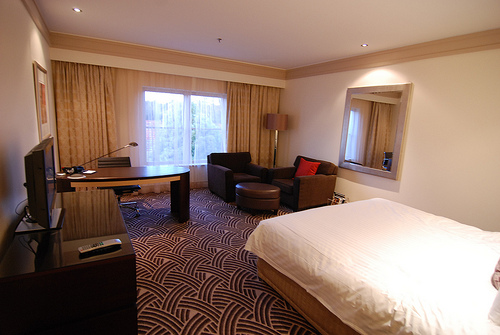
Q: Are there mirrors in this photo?
A: Yes, there is a mirror.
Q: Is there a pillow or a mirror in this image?
A: Yes, there is a mirror.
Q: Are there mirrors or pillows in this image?
A: Yes, there is a mirror.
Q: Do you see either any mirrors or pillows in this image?
A: Yes, there is a mirror.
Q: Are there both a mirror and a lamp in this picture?
A: Yes, there are both a mirror and a lamp.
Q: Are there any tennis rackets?
A: No, there are no tennis rackets.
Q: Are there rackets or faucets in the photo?
A: No, there are no rackets or faucets.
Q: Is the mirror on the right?
A: Yes, the mirror is on the right of the image.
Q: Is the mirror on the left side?
A: No, the mirror is on the right of the image.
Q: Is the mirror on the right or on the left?
A: The mirror is on the right of the image.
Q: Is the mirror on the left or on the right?
A: The mirror is on the right of the image.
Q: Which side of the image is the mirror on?
A: The mirror is on the right of the image.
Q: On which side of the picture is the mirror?
A: The mirror is on the right of the image.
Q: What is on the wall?
A: The mirror is on the wall.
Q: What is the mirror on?
A: The mirror is on the wall.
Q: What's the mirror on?
A: The mirror is on the wall.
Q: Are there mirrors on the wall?
A: Yes, there is a mirror on the wall.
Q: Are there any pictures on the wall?
A: No, there is a mirror on the wall.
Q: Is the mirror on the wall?
A: Yes, the mirror is on the wall.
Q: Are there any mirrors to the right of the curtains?
A: Yes, there is a mirror to the right of the curtains.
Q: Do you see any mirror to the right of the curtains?
A: Yes, there is a mirror to the right of the curtains.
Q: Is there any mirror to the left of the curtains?
A: No, the mirror is to the right of the curtains.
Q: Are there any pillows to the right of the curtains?
A: No, there is a mirror to the right of the curtains.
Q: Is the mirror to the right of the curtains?
A: Yes, the mirror is to the right of the curtains.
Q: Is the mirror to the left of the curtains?
A: No, the mirror is to the right of the curtains.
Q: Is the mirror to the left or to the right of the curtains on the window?
A: The mirror is to the right of the curtains.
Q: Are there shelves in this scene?
A: No, there are no shelves.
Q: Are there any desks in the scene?
A: Yes, there is a desk.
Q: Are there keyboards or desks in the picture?
A: Yes, there is a desk.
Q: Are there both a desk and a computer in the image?
A: No, there is a desk but no computers.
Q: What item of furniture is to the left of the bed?
A: The piece of furniture is a desk.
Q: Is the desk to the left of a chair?
A: No, the desk is to the left of the bed.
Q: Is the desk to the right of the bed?
A: No, the desk is to the left of the bed.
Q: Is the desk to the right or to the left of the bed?
A: The desk is to the left of the bed.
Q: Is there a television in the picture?
A: Yes, there is a television.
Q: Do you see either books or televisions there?
A: Yes, there is a television.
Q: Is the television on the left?
A: Yes, the television is on the left of the image.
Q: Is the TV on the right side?
A: No, the TV is on the left of the image.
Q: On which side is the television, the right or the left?
A: The television is on the left of the image.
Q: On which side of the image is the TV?
A: The TV is on the left of the image.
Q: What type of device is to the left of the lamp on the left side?
A: The device is a television.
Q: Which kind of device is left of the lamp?
A: The device is a television.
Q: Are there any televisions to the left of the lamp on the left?
A: Yes, there is a television to the left of the lamp.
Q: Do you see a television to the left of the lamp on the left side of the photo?
A: Yes, there is a television to the left of the lamp.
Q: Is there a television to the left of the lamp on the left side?
A: Yes, there is a television to the left of the lamp.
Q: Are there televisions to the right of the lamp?
A: No, the television is to the left of the lamp.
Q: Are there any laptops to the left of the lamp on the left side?
A: No, there is a television to the left of the lamp.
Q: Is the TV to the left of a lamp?
A: Yes, the TV is to the left of a lamp.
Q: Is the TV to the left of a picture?
A: No, the TV is to the left of a lamp.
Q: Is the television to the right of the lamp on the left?
A: No, the television is to the left of the lamp.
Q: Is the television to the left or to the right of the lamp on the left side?
A: The television is to the left of the lamp.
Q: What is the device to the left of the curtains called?
A: The device is a television.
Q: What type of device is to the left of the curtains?
A: The device is a television.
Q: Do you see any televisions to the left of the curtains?
A: Yes, there is a television to the left of the curtains.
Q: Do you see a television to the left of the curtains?
A: Yes, there is a television to the left of the curtains.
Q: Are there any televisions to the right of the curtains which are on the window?
A: No, the television is to the left of the curtains.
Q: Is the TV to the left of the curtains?
A: Yes, the TV is to the left of the curtains.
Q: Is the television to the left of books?
A: No, the television is to the left of the curtains.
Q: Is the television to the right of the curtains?
A: No, the television is to the left of the curtains.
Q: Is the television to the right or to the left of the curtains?
A: The television is to the left of the curtains.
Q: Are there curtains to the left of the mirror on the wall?
A: Yes, there are curtains to the left of the mirror.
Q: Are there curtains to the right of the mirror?
A: No, the curtains are to the left of the mirror.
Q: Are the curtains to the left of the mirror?
A: Yes, the curtains are to the left of the mirror.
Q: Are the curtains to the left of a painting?
A: No, the curtains are to the left of the mirror.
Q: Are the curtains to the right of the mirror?
A: No, the curtains are to the left of the mirror.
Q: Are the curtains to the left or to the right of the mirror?
A: The curtains are to the left of the mirror.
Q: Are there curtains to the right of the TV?
A: Yes, there are curtains to the right of the TV.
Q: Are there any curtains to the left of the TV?
A: No, the curtains are to the right of the TV.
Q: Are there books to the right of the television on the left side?
A: No, there are curtains to the right of the television.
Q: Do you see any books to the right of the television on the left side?
A: No, there are curtains to the right of the television.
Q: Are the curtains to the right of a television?
A: Yes, the curtains are to the right of a television.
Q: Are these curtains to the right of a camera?
A: No, the curtains are to the right of a television.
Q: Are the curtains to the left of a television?
A: No, the curtains are to the right of a television.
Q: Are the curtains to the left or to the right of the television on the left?
A: The curtains are to the right of the TV.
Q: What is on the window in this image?
A: The curtains are on the window.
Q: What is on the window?
A: The curtains are on the window.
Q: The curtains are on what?
A: The curtains are on the window.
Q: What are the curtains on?
A: The curtains are on the window.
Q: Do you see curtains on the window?
A: Yes, there are curtains on the window.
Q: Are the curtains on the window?
A: Yes, the curtains are on the window.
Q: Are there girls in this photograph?
A: No, there are no girls.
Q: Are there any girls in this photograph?
A: No, there are no girls.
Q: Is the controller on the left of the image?
A: Yes, the controller is on the left of the image.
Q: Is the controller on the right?
A: No, the controller is on the left of the image.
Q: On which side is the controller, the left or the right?
A: The controller is on the left of the image.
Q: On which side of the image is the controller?
A: The controller is on the left of the image.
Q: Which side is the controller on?
A: The controller is on the left of the image.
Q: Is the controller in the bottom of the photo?
A: Yes, the controller is in the bottom of the image.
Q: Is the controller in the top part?
A: No, the controller is in the bottom of the image.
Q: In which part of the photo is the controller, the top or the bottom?
A: The controller is in the bottom of the image.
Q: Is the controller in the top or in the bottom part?
A: The controller is in the bottom of the image.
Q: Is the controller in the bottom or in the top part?
A: The controller is in the bottom of the image.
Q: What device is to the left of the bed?
A: The device is a controller.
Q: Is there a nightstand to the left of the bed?
A: No, there is a controller to the left of the bed.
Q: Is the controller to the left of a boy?
A: No, the controller is to the left of the bed.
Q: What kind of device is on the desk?
A: The device is a controller.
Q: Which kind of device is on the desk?
A: The device is a controller.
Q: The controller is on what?
A: The controller is on the desk.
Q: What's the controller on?
A: The controller is on the desk.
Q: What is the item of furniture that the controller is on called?
A: The piece of furniture is a desk.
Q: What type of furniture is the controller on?
A: The controller is on the desk.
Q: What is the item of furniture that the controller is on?
A: The piece of furniture is a desk.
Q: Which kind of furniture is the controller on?
A: The controller is on the desk.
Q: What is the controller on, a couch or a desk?
A: The controller is on a desk.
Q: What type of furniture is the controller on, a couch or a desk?
A: The controller is on a desk.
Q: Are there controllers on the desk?
A: Yes, there is a controller on the desk.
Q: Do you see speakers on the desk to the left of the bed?
A: No, there is a controller on the desk.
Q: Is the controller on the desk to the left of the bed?
A: Yes, the controller is on the desk.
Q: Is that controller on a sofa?
A: No, the controller is on the desk.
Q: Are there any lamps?
A: Yes, there is a lamp.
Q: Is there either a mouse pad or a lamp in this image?
A: Yes, there is a lamp.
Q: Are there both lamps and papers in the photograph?
A: No, there is a lamp but no papers.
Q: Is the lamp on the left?
A: Yes, the lamp is on the left of the image.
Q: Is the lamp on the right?
A: No, the lamp is on the left of the image.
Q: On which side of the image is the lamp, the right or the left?
A: The lamp is on the left of the image.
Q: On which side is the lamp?
A: The lamp is on the left of the image.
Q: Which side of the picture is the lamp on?
A: The lamp is on the left of the image.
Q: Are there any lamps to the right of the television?
A: Yes, there is a lamp to the right of the television.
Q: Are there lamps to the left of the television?
A: No, the lamp is to the right of the television.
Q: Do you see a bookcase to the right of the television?
A: No, there is a lamp to the right of the television.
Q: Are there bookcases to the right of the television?
A: No, there is a lamp to the right of the television.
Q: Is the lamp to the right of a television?
A: Yes, the lamp is to the right of a television.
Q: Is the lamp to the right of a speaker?
A: No, the lamp is to the right of a television.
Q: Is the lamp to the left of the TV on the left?
A: No, the lamp is to the right of the television.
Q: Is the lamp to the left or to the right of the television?
A: The lamp is to the right of the television.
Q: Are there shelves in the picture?
A: No, there are no shelves.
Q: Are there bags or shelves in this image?
A: No, there are no shelves or bags.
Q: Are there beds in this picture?
A: Yes, there is a bed.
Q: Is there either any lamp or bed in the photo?
A: Yes, there is a bed.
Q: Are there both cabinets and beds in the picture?
A: No, there is a bed but no cabinets.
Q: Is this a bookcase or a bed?
A: This is a bed.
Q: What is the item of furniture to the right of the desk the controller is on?
A: The piece of furniture is a bed.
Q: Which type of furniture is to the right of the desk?
A: The piece of furniture is a bed.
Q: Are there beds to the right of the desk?
A: Yes, there is a bed to the right of the desk.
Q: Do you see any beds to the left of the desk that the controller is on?
A: No, the bed is to the right of the desk.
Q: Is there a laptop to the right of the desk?
A: No, there is a bed to the right of the desk.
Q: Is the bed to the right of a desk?
A: Yes, the bed is to the right of a desk.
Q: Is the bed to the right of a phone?
A: No, the bed is to the right of a desk.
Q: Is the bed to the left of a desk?
A: No, the bed is to the right of a desk.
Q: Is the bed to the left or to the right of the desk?
A: The bed is to the right of the desk.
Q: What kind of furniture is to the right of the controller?
A: The piece of furniture is a bed.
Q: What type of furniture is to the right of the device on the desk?
A: The piece of furniture is a bed.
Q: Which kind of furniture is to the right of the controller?
A: The piece of furniture is a bed.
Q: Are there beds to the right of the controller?
A: Yes, there is a bed to the right of the controller.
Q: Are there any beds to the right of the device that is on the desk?
A: Yes, there is a bed to the right of the controller.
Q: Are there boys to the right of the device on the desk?
A: No, there is a bed to the right of the controller.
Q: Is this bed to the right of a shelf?
A: No, the bed is to the right of the controller.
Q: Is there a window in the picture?
A: Yes, there is a window.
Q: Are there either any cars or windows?
A: Yes, there is a window.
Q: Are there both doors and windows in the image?
A: No, there is a window but no doors.